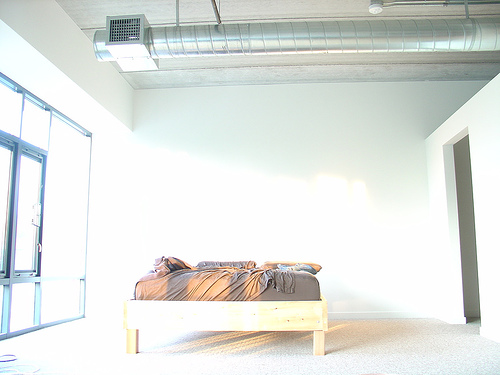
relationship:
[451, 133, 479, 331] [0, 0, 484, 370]
door in room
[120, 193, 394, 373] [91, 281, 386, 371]
bed with frame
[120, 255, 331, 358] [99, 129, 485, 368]
bed in room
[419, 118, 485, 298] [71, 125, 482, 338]
doorway of room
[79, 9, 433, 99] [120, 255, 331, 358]
vent above bed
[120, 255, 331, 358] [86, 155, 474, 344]
bed in room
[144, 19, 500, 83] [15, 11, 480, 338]
ducting above bedroom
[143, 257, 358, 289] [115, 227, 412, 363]
pillows on bed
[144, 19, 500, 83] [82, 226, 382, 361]
ducting above bed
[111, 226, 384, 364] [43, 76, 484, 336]
frame in room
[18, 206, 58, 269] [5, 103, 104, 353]
latch to window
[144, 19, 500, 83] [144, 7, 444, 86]
ducting holding ducting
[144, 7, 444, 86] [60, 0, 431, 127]
ducting to ceiling